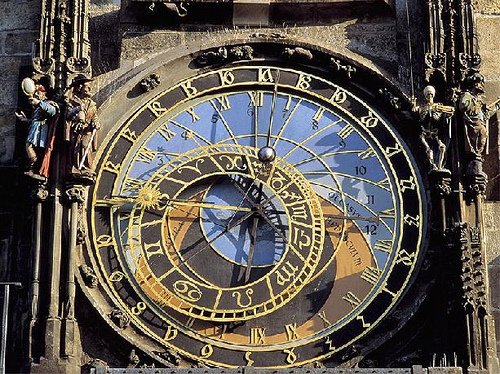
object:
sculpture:
[13, 76, 59, 184]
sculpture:
[62, 74, 100, 185]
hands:
[107, 194, 286, 284]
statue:
[401, 84, 455, 176]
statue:
[456, 68, 499, 178]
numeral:
[373, 240, 392, 254]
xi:
[342, 291, 362, 309]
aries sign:
[177, 159, 205, 176]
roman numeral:
[312, 106, 327, 124]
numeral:
[284, 322, 299, 340]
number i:
[284, 96, 292, 110]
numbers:
[247, 91, 264, 107]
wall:
[1, 0, 498, 374]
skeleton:
[409, 67, 500, 199]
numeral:
[360, 266, 383, 285]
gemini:
[144, 240, 165, 261]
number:
[336, 124, 355, 141]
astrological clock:
[74, 33, 440, 369]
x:
[317, 311, 332, 328]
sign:
[172, 279, 201, 303]